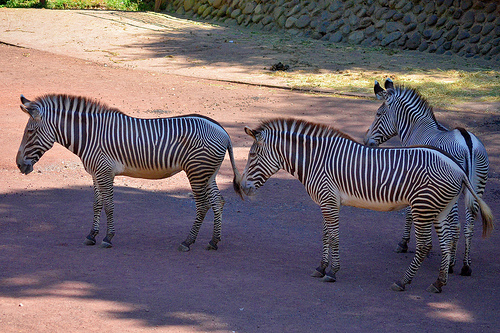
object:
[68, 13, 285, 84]
part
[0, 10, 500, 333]
ground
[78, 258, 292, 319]
part